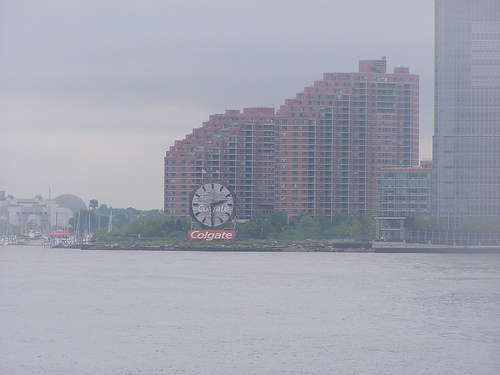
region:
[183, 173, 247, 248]
the clock in the grass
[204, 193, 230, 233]
the black hands of the clock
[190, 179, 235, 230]
the round clear face fo the clock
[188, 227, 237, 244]
the red sign under the clock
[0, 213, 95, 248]
the boats on the water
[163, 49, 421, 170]
the red step roof for the building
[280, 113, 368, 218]
the windows on the building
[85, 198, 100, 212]
the round water tank above the trees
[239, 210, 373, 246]
the trees in front of the red building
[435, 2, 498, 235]
the tal grye skyscrapper in front of the water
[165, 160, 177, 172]
window of a building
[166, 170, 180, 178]
window of a building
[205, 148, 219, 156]
window of a building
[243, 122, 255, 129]
window of a building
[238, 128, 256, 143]
window of a building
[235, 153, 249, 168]
window of a building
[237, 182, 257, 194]
window of a building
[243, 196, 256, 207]
window of a building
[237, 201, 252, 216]
window of a building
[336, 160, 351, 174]
window of a building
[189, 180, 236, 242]
A large clock with colgate underneath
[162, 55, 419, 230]
building is made out of brick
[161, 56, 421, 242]
clock is in front of brick building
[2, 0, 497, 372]
buildings are beside water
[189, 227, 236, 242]
colgate sign is red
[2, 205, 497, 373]
boats are floating in the water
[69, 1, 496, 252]
trees are in front of building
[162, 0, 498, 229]
brick building is beside tall building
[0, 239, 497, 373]
rocks are near the shoreline of the water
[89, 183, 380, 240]
trees are behind the clock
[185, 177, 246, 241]
a colgate clock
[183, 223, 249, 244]
a red and white sign for colgate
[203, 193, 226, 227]
minute hand a hour hand on a clock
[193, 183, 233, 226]
the face of a clock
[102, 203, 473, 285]
trees on the side of the water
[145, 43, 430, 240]
a large red building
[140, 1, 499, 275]
two tall buildings next to eachother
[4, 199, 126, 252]
several boats in the harbor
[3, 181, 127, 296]
several boats floating on the water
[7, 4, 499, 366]
a cloudy view of the edge of a city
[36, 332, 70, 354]
Small ripples in the water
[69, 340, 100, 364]
Small ripples in the water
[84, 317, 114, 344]
Small ripples in the water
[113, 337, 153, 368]
Small ripples in the water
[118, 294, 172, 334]
Small ripples in the water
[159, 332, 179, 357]
Small ripples in the water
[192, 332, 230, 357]
Small ripples in the water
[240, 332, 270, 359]
Small ripples in the water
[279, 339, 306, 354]
Small ripples in the water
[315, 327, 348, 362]
Small ripples in the water